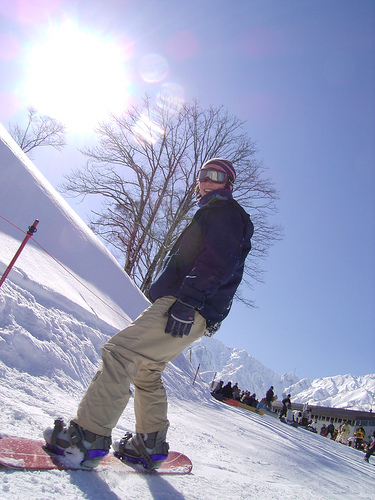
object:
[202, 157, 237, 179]
hat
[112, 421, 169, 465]
boots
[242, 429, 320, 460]
snow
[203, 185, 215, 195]
mouth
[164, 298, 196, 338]
blue gloves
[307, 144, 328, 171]
ground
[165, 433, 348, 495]
ground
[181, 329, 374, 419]
mountains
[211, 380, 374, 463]
people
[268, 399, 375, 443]
building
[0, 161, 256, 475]
snowboarder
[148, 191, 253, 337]
coat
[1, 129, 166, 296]
snowboard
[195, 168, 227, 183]
eyewear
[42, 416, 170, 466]
pair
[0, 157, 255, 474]
snowboard gear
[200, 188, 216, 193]
smile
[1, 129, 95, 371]
pile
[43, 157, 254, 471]
individual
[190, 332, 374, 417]
distance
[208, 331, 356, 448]
background